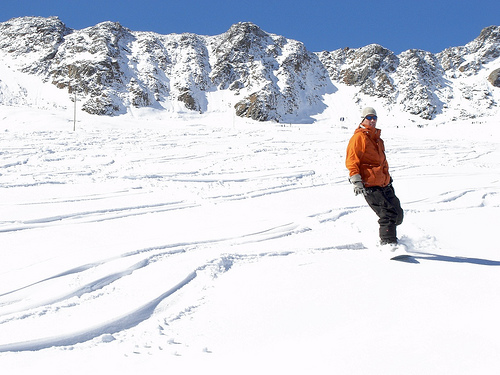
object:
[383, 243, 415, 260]
snowboard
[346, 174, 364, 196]
glove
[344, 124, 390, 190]
jacket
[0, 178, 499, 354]
tracks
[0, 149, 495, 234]
tracks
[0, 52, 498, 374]
snow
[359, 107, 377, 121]
beanie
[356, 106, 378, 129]
head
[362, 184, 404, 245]
pants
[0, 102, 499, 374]
ski slope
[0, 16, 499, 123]
mountains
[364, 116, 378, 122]
sunglasses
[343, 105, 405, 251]
man